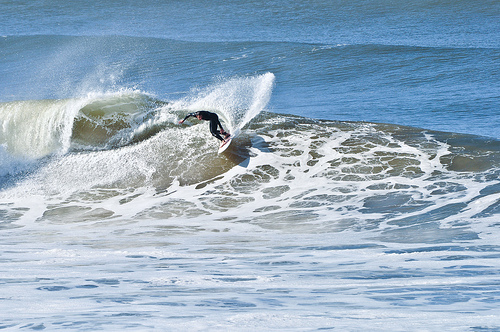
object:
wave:
[0, 86, 150, 162]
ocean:
[0, 0, 500, 332]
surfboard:
[218, 134, 236, 154]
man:
[177, 110, 233, 149]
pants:
[209, 119, 228, 141]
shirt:
[183, 110, 223, 128]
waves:
[0, 70, 283, 184]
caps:
[139, 153, 156, 164]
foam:
[255, 143, 456, 238]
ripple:
[317, 65, 495, 105]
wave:
[0, 20, 500, 64]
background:
[0, 0, 500, 141]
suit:
[183, 111, 228, 142]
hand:
[178, 120, 183, 124]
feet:
[221, 139, 226, 144]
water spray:
[174, 69, 277, 134]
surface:
[147, 72, 291, 169]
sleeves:
[182, 111, 196, 121]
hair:
[194, 110, 206, 116]